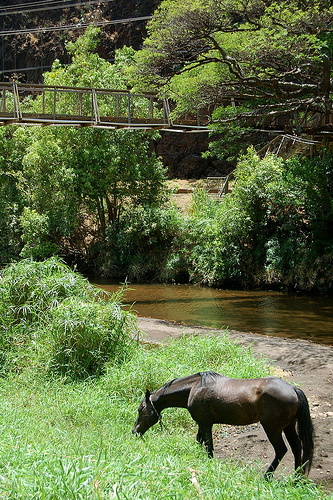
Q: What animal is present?
A: A horse.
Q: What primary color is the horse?
A: Brown.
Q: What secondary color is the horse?
A: Black.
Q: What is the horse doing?
A: Grazing.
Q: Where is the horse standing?
A: A river bank.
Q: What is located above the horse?
A: A bridge.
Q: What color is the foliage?
A: Green.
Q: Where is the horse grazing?
A: On a river bank.